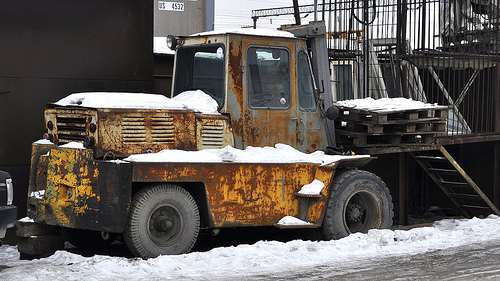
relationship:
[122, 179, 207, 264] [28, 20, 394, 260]
tire on vehicle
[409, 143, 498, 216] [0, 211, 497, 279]
ladder on snow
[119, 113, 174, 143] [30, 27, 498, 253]
vent on forklift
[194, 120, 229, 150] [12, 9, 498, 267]
vent on forklift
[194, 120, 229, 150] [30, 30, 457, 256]
vent on forklift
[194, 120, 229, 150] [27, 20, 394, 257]
vent on forklift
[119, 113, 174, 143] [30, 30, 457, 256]
vent on forklift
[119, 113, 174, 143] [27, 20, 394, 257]
vent on forklift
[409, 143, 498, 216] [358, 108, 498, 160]
ladder under dock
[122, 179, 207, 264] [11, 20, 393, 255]
tire of a forklift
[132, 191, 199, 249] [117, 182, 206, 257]
tire on wheel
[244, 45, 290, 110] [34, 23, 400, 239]
window on truck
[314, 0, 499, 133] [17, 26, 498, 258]
fence behind a loader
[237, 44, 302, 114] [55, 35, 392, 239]
side window of vehicle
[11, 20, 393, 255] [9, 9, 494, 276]
forklift in photo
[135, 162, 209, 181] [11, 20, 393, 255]
rust on forklift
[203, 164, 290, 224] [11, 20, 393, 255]
rust on forklift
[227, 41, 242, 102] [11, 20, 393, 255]
rust on forklift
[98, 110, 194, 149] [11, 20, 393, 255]
rust on forklift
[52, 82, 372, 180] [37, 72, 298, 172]
snow on hood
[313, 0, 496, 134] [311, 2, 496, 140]
bars on gate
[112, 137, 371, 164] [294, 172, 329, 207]
snow piles on step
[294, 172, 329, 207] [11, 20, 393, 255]
step on forklift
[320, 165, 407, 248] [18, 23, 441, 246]
tire on loader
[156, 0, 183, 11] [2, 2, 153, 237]
number on building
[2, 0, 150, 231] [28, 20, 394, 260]
wall next to vehicle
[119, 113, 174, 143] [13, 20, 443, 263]
vent on a forklift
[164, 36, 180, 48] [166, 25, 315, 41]
flood light on roof